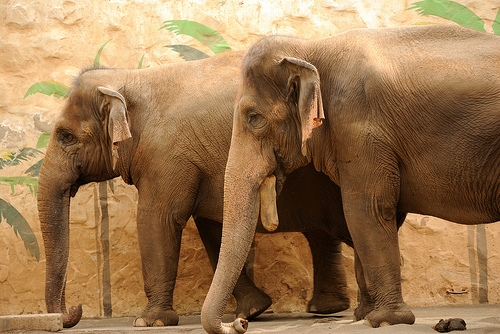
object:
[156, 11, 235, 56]
leaves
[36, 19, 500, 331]
two elephants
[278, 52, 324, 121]
border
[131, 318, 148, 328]
nail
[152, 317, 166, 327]
nail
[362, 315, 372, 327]
nail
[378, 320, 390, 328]
nail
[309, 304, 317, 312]
nail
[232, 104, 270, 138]
eye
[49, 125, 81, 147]
eye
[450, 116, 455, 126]
ground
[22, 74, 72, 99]
tree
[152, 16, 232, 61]
tree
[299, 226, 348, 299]
legs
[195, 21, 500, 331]
elephant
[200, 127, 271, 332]
trunk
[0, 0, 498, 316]
walls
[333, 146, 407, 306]
leg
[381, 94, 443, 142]
skin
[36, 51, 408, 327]
elephant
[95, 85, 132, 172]
ear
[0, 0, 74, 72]
brown wall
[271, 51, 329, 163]
ear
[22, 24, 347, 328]
brown potato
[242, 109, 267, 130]
eye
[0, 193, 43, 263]
leaves